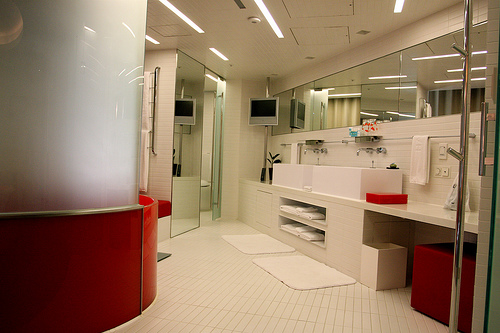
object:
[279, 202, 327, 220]
towels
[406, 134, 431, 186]
towels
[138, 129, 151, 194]
towels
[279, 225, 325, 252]
shelf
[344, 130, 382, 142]
shelf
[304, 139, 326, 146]
shelf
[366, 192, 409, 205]
box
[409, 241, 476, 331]
seat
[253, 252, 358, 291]
floor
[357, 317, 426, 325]
ground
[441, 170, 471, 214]
bag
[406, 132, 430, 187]
towel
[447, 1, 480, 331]
metal pole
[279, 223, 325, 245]
towels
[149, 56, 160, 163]
towel rack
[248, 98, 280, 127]
monitor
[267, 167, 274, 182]
pot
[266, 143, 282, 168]
plant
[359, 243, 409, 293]
trash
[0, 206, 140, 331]
wall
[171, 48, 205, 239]
mirror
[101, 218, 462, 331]
floor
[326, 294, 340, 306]
tile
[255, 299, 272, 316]
tile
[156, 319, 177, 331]
tile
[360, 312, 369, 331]
tile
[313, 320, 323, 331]
tile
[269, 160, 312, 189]
white sinks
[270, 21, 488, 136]
mirror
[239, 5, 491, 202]
wall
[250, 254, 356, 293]
rug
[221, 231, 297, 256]
rug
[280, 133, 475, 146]
rack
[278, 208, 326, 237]
shelf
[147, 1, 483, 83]
ceiling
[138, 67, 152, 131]
towels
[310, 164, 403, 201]
sink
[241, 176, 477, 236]
counter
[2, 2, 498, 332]
bathroom